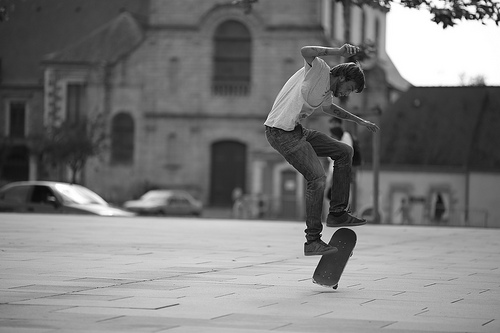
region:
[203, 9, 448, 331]
man riding skateboard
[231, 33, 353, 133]
man wearing white shirt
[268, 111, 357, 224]
man wearing blue jeans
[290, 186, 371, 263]
man wearing dark shoes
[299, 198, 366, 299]
front end of skateboard up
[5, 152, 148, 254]
car parked in background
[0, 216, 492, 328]
cement tiles on walkway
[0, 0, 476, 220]
large building in background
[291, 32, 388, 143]
man has arms up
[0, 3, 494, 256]
multiple windows on building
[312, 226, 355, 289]
the skateboard in mid air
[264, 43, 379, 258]
the man in mid air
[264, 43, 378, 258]
the man above the skateboard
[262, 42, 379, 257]
the man who is skateboarding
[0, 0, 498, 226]
the large building in the background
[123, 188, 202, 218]
the car near the building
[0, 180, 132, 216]
the parked car across the building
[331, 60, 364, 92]
the hair on the man's head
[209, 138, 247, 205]
the door to the building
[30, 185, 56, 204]
the car's passenger window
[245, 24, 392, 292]
person wearing a pair of jeans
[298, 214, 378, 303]
a skateboard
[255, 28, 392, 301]
person riding on a skateboard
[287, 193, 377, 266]
a pair of sneakers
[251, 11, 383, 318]
person wearing a white shirt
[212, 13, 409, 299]
person jumping off of skateboard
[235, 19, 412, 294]
person wearing a pair of sneakers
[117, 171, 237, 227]
car parked on street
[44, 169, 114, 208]
windshield of a car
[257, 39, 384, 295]
A guy doing a trick on a skateboard.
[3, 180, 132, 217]
The top of a car.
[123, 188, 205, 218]
A parked car.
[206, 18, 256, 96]
A window on a building.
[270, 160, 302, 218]
A door.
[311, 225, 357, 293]
A skateboard flipped in the air.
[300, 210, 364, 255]
Dark tennis shoes.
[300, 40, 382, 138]
A guy's arms in the air.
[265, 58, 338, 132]
A mostly white t-shirt.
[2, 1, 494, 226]
A large building.